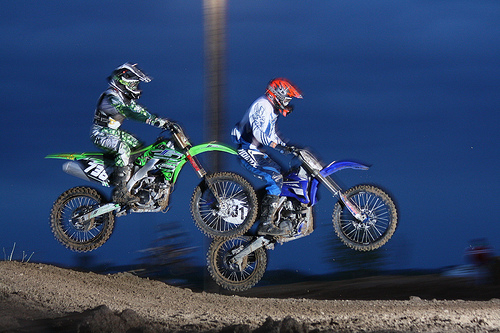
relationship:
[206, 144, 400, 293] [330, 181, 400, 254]
motorbike has front wheel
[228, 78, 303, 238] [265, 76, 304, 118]
rider wearing helmet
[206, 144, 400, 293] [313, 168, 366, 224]
motorbike has suspension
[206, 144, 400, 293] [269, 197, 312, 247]
motorbike has engine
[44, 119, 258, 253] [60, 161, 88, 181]
motorbike has tail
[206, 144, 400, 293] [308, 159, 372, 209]
motorbike has mud guard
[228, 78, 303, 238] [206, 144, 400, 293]
rider on motorbike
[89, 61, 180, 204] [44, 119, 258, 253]
rider on motorbike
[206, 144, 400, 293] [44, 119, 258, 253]
motorbike next to motorbike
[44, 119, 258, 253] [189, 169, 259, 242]
motorbike has front wheel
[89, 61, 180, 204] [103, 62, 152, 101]
rider wearing helmet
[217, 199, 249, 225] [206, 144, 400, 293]
number on motorbike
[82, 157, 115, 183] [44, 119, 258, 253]
number on motorbike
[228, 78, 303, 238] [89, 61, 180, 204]
rider racing rider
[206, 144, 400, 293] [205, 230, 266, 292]
motorbike has back wheel